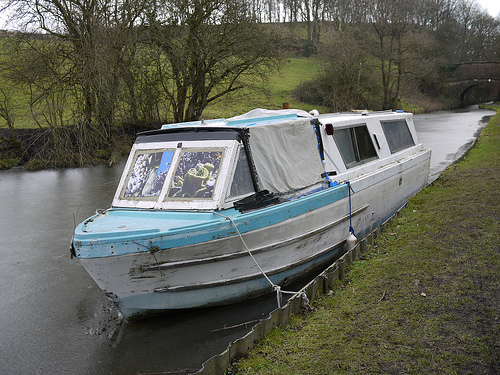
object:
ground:
[390, 183, 500, 374]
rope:
[210, 207, 309, 308]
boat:
[70, 105, 429, 315]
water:
[2, 86, 488, 372]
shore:
[283, 146, 500, 370]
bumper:
[334, 227, 363, 258]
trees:
[11, 2, 267, 113]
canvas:
[238, 115, 336, 195]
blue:
[65, 181, 351, 262]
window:
[104, 136, 240, 213]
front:
[65, 122, 254, 317]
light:
[5, 4, 499, 371]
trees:
[213, 0, 499, 34]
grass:
[345, 174, 500, 370]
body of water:
[430, 96, 496, 150]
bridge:
[433, 59, 499, 89]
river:
[0, 167, 76, 373]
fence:
[180, 241, 382, 372]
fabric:
[152, 100, 335, 201]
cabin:
[113, 104, 325, 205]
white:
[346, 103, 440, 214]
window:
[327, 124, 380, 168]